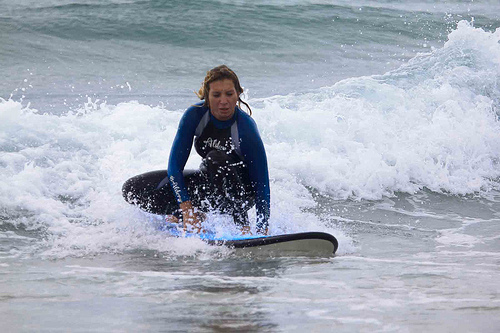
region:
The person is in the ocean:
[20, 15, 485, 320]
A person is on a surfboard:
[60, 55, 401, 288]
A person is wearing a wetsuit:
[38, 33, 431, 274]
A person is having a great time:
[38, 33, 445, 313]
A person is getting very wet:
[45, 48, 380, 293]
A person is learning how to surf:
[43, 46, 395, 306]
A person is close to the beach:
[6, 45, 446, 310]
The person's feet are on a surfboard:
[15, 26, 421, 311]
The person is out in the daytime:
[11, 25, 456, 298]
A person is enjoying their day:
[39, 33, 445, 330]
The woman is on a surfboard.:
[106, 54, 350, 281]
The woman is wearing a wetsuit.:
[107, 58, 347, 273]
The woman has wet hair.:
[119, 56, 348, 286]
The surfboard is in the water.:
[108, 59, 353, 281]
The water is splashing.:
[1, 0, 498, 330]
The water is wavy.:
[1, 0, 498, 331]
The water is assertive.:
[2, 3, 499, 331]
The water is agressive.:
[1, 1, 498, 331]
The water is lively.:
[1, 0, 498, 331]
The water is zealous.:
[1, 0, 499, 332]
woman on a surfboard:
[106, 64, 340, 261]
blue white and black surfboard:
[154, 220, 343, 259]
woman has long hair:
[183, 63, 258, 123]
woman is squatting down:
[103, 63, 282, 239]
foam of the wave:
[3, 25, 495, 215]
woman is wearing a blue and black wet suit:
[103, 60, 287, 239]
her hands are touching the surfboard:
[177, 200, 284, 242]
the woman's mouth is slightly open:
[211, 105, 236, 115]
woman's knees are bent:
[122, 150, 247, 213]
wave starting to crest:
[0, 3, 499, 103]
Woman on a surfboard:
[118, 40, 383, 293]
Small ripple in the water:
[407, 140, 494, 219]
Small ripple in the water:
[375, 161, 435, 214]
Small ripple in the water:
[304, 163, 371, 221]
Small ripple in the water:
[94, 215, 226, 297]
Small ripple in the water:
[10, 193, 92, 295]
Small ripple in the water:
[350, 46, 438, 98]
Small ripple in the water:
[285, 66, 379, 121]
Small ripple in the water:
[113, 79, 193, 132]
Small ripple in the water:
[25, 65, 109, 128]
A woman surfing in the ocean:
[116, 60, 346, 265]